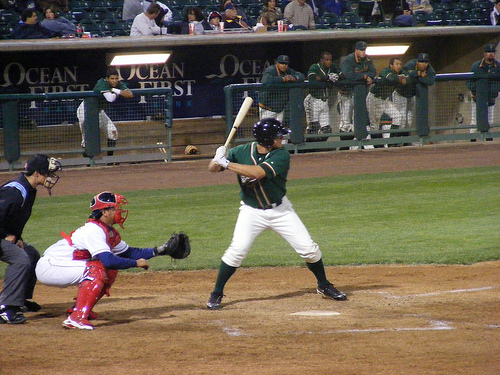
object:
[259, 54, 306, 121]
player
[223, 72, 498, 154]
rail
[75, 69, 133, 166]
baseball player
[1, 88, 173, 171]
rail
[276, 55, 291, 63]
baseball hat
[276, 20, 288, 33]
soda cup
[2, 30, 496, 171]
dugout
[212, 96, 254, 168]
baseball bat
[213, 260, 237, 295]
sock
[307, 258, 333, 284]
sock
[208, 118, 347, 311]
player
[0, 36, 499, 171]
dugout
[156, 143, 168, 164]
bats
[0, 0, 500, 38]
spectators